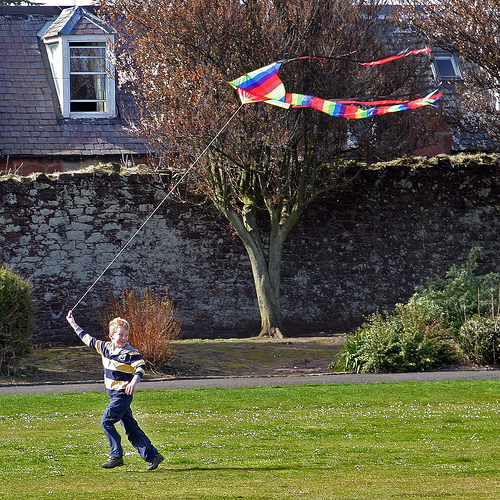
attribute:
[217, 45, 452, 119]
kite — colorful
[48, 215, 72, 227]
rock — grey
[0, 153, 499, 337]
wall — grey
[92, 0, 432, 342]
tree — wood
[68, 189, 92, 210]
rock — grey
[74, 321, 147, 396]
shirt — striped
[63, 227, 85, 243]
rock — grey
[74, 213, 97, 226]
rock — grey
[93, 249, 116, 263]
rock — grey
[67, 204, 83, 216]
rock — grey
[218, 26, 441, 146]
kite — multi colored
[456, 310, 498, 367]
bush — green 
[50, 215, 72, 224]
rock — grey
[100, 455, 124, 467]
black shoe — black 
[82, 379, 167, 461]
pants — blue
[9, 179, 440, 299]
wall — gray, stone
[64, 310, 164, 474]
boy — young